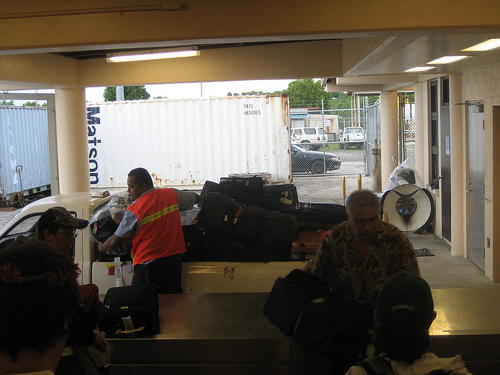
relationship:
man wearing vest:
[95, 165, 196, 286] [127, 187, 187, 266]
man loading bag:
[98, 168, 201, 295] [187, 184, 245, 260]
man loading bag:
[98, 168, 201, 295] [84, 211, 131, 259]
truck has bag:
[2, 184, 350, 294] [187, 184, 245, 260]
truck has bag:
[2, 184, 350, 294] [84, 211, 131, 259]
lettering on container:
[80, 101, 117, 194] [87, 102, 322, 194]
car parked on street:
[291, 144, 341, 174] [325, 149, 365, 163]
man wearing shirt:
[264, 186, 443, 366] [313, 223, 425, 308]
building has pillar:
[347, 39, 497, 109] [449, 74, 465, 258]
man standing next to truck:
[98, 168, 201, 295] [0, 192, 310, 347]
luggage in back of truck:
[198, 191, 299, 247] [2, 184, 350, 294]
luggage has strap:
[194, 174, 308, 269] [220, 207, 241, 233]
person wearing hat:
[3, 202, 127, 372] [32, 204, 95, 241]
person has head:
[205, 132, 427, 238] [119, 161, 155, 201]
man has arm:
[98, 168, 201, 295] [94, 211, 139, 254]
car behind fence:
[282, 134, 345, 176] [295, 97, 377, 185]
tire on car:
[307, 157, 328, 177] [284, 131, 348, 173]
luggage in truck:
[198, 191, 299, 247] [8, 185, 390, 299]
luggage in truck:
[292, 231, 324, 253] [10, 207, 312, 279]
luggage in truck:
[198, 191, 299, 247] [98, 95, 305, 184]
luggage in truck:
[198, 191, 299, 247] [88, 92, 389, 222]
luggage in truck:
[217, 175, 267, 205] [212, 188, 304, 248]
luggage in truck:
[198, 191, 299, 247] [212, 188, 304, 248]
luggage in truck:
[198, 191, 299, 247] [3, 191, 315, 291]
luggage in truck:
[83, 190, 145, 265] [5, 175, 431, 370]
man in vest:
[98, 168, 201, 295] [125, 182, 194, 264]